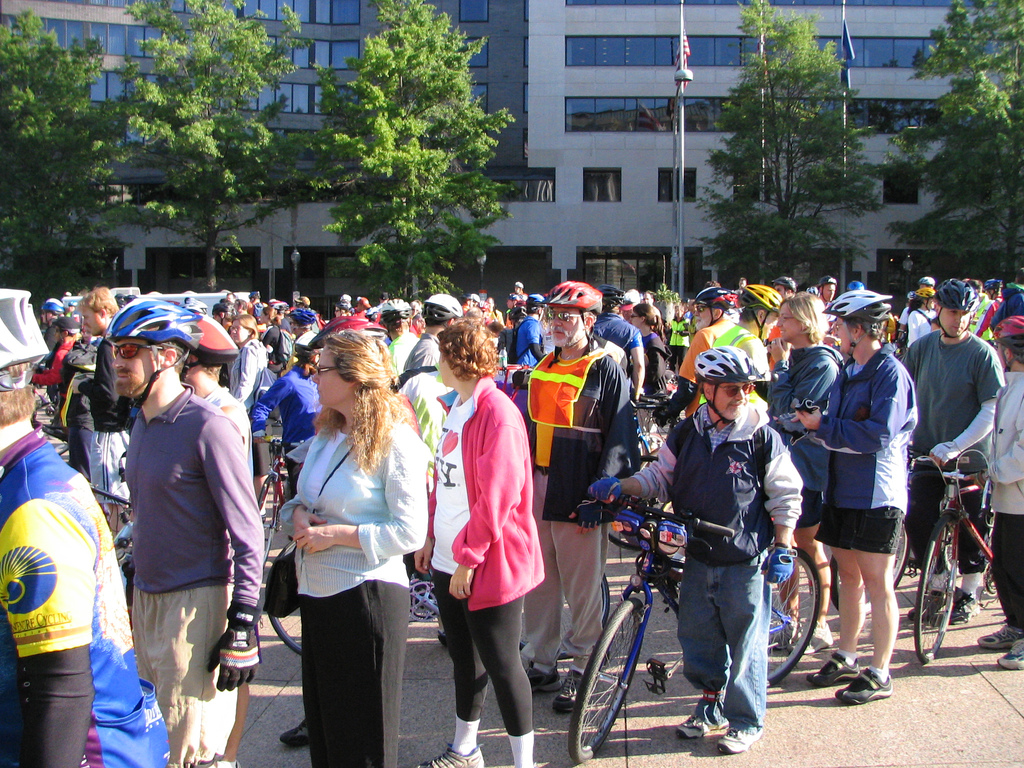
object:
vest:
[528, 328, 656, 478]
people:
[916, 280, 1024, 679]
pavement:
[492, 571, 1024, 767]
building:
[524, 1, 991, 300]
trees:
[695, 0, 887, 280]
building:
[0, 0, 527, 302]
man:
[484, 276, 636, 721]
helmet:
[681, 284, 737, 308]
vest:
[11, 470, 201, 767]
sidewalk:
[796, 685, 996, 758]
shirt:
[422, 386, 574, 611]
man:
[82, 292, 281, 766]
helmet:
[525, 280, 614, 319]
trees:
[877, 0, 1023, 286]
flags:
[662, 17, 703, 70]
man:
[591, 328, 812, 765]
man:
[896, 266, 1006, 638]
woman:
[408, 305, 555, 765]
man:
[510, 266, 634, 720]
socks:
[441, 712, 495, 752]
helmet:
[95, 297, 215, 349]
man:
[900, 271, 1005, 629]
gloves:
[567, 481, 620, 530]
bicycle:
[910, 448, 1023, 671]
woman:
[266, 318, 442, 765]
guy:
[580, 333, 821, 765]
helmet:
[818, 282, 898, 333]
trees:
[288, 2, 520, 293]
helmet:
[930, 277, 985, 314]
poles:
[648, 33, 706, 296]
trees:
[81, 4, 309, 296]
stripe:
[529, 363, 587, 389]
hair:
[350, 344, 388, 475]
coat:
[428, 380, 551, 613]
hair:
[443, 340, 493, 371]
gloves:
[751, 547, 803, 591]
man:
[109, 296, 281, 764]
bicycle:
[560, 526, 833, 767]